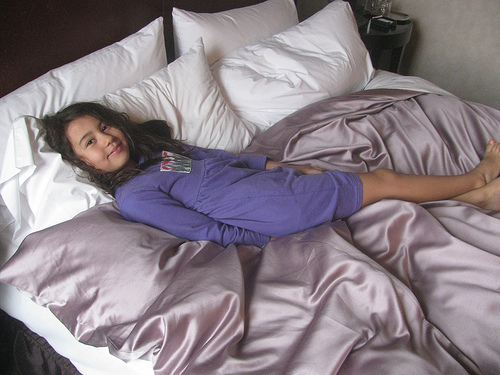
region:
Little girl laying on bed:
[51, 77, 494, 240]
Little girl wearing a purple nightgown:
[120, 118, 427, 269]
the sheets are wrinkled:
[167, 278, 351, 373]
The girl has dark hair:
[40, 95, 165, 165]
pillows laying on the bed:
[15, 57, 358, 206]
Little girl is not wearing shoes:
[428, 87, 493, 178]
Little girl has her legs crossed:
[367, 110, 492, 192]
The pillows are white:
[196, 35, 356, 117]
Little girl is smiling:
[47, 103, 198, 208]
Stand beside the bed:
[350, 5, 440, 116]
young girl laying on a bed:
[38, 82, 497, 234]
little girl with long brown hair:
[23, 76, 497, 260]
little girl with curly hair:
[29, 89, 494, 256]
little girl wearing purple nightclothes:
[32, 97, 499, 249]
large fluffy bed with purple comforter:
[4, 2, 499, 372]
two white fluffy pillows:
[173, 5, 383, 135]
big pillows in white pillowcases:
[169, 1, 389, 146]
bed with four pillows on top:
[2, 0, 493, 371]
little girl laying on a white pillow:
[31, 80, 499, 278]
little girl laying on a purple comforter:
[31, 92, 499, 258]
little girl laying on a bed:
[19, 73, 497, 324]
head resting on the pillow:
[33, 96, 165, 192]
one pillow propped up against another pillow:
[175, 0, 442, 125]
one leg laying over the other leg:
[371, 128, 499, 234]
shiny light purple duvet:
[3, 88, 499, 373]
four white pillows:
[2, 0, 385, 237]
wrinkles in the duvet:
[169, 273, 253, 373]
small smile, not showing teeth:
[97, 139, 129, 161]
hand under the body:
[223, 211, 315, 256]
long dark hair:
[39, 96, 214, 211]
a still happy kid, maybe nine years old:
[37, 92, 498, 257]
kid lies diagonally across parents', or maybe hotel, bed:
[0, 0, 498, 373]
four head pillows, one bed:
[1, 0, 383, 269]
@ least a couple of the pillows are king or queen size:
[1, 2, 391, 219]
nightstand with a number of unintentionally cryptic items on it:
[326, 0, 418, 78]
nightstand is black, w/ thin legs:
[339, 2, 421, 84]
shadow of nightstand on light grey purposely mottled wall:
[365, 0, 498, 114]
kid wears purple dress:
[107, 103, 376, 258]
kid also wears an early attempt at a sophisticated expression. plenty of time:
[61, 112, 137, 174]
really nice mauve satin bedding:
[0, 85, 498, 372]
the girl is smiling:
[42, 96, 202, 199]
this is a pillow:
[0, 33, 270, 255]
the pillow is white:
[1, 0, 383, 255]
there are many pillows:
[1, 0, 378, 250]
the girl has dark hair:
[37, 102, 201, 192]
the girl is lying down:
[35, 100, 497, 252]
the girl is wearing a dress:
[111, 133, 370, 264]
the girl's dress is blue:
[111, 137, 368, 259]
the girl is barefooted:
[456, 134, 498, 219]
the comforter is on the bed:
[0, 80, 499, 373]